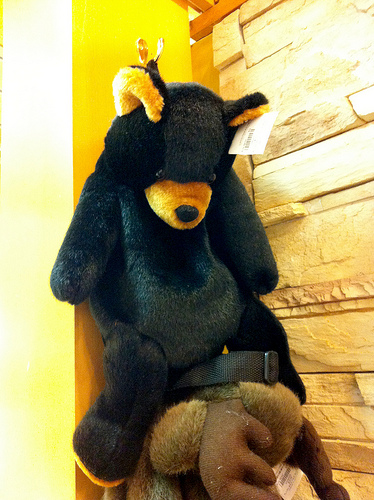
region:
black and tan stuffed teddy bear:
[54, 50, 306, 471]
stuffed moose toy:
[121, 378, 341, 497]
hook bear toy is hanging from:
[142, 36, 170, 69]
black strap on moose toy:
[178, 348, 276, 387]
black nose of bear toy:
[175, 204, 199, 223]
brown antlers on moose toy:
[199, 399, 355, 498]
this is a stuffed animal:
[54, 43, 321, 490]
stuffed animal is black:
[50, 47, 350, 498]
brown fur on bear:
[132, 161, 221, 237]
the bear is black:
[50, 80, 329, 487]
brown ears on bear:
[89, 50, 280, 141]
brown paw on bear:
[63, 433, 132, 497]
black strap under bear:
[172, 332, 312, 396]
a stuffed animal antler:
[192, 379, 286, 497]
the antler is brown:
[196, 383, 287, 497]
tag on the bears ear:
[217, 90, 278, 162]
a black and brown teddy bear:
[47, 64, 304, 486]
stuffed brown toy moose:
[102, 380, 348, 498]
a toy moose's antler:
[193, 401, 281, 498]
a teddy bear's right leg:
[72, 327, 167, 487]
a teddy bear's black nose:
[168, 204, 201, 223]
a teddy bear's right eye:
[150, 164, 168, 181]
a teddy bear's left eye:
[207, 168, 223, 186]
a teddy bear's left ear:
[223, 89, 268, 130]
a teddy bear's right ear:
[112, 65, 165, 123]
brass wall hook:
[135, 33, 163, 68]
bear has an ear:
[113, 66, 164, 121]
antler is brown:
[193, 403, 282, 498]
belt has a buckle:
[174, 350, 278, 385]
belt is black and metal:
[172, 350, 279, 384]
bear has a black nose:
[174, 202, 198, 220]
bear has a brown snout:
[140, 179, 212, 227]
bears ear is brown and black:
[225, 92, 268, 128]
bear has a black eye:
[151, 168, 162, 177]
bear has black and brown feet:
[73, 412, 144, 490]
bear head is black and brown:
[104, 87, 234, 228]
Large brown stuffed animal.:
[100, 381, 350, 498]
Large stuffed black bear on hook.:
[49, 61, 305, 487]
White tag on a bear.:
[226, 110, 278, 153]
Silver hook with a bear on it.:
[136, 37, 163, 64]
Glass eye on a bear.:
[153, 168, 167, 180]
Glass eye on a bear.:
[207, 172, 217, 184]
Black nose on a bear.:
[174, 204, 198, 221]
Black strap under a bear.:
[164, 350, 279, 390]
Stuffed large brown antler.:
[198, 397, 280, 499]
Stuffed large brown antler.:
[293, 415, 350, 498]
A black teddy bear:
[49, 62, 304, 487]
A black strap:
[164, 348, 274, 381]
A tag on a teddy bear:
[228, 101, 279, 157]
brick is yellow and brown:
[211, 7, 243, 70]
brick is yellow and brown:
[296, 372, 364, 404]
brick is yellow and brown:
[303, 404, 373, 441]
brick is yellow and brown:
[321, 438, 373, 472]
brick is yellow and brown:
[295, 468, 373, 498]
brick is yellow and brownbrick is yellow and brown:
[257, 272, 373, 306]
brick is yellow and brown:
[303, 178, 371, 211]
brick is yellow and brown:
[264, 196, 369, 287]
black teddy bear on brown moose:
[49, 58, 349, 498]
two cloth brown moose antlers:
[196, 396, 351, 498]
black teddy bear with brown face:
[46, 56, 307, 487]